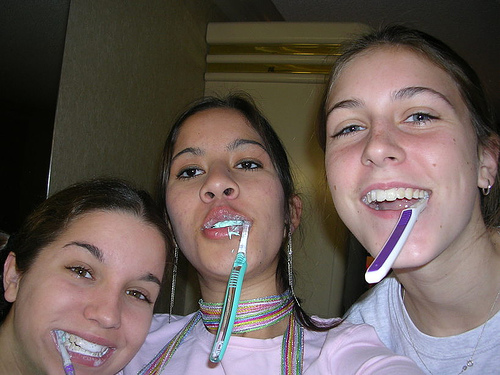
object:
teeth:
[60, 341, 88, 351]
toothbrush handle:
[205, 241, 250, 364]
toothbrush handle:
[55, 351, 71, 373]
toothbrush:
[49, 330, 78, 374]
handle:
[365, 208, 423, 287]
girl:
[114, 89, 426, 374]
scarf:
[138, 287, 306, 373]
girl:
[0, 176, 170, 374]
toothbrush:
[183, 215, 250, 370]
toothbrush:
[359, 191, 429, 283]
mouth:
[353, 175, 433, 219]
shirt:
[346, 272, 498, 374]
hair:
[132, 77, 307, 320]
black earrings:
[477, 177, 492, 195]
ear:
[477, 141, 497, 191]